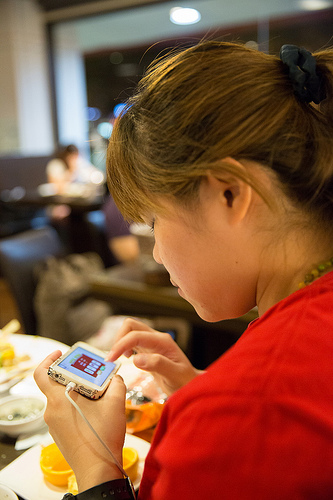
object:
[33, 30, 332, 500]
woman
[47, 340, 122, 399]
cellphone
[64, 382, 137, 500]
cord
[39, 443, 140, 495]
oranges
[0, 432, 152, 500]
plate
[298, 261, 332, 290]
round beads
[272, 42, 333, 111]
scrunchie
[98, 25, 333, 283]
hair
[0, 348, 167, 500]
table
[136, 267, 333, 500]
shirt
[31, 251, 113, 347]
bag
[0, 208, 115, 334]
booth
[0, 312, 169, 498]
food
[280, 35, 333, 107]
tie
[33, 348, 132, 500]
left hand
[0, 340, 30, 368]
food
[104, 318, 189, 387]
fingers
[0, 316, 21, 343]
chopstick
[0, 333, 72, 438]
plate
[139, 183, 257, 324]
face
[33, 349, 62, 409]
fingers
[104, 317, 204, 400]
right hand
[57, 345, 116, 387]
screen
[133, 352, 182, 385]
thumb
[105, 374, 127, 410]
thumb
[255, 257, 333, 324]
neck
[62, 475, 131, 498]
watch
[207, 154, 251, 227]
ear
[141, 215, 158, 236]
eye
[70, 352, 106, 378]
red square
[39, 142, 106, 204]
person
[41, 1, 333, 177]
window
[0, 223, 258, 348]
chair and table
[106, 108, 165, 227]
bangs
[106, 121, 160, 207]
forehead